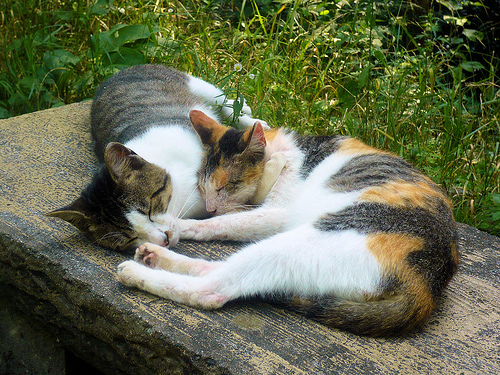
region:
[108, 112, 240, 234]
two cats are sleeping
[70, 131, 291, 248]
two cats are sleeping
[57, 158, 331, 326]
two cats are sleeping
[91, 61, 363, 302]
two cats are sleeping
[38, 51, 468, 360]
two cats, who are friends -or- momcat+kitten. hard to tell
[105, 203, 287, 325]
smaller cat has pink skin, seen beneath forelegs, lower hindlegs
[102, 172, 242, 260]
at least three, likely four, closed sleep eyes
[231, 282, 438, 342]
little cat's tail curled beneath little cat's thigh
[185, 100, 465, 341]
little calico has a vary bright orange in the mix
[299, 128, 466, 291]
three large grey+black stripe+spots on little, mostly white, calico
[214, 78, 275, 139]
two white hind feet of larger cat, with fluffy dandelions beside them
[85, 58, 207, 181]
long grey brown stripes on side of larger animal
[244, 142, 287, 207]
collar, other cat's forepaw, or bandage around little cat's neck? i am unsure, i am sorry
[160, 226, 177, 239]
one tiny light brown dot @ left side of larger cat's nose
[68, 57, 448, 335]
two reclined cats on bench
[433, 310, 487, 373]
grain of wood bench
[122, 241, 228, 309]
white feet on cat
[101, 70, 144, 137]
stripes on cat body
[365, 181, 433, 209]
orange on cat back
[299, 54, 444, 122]
green vegetation behind bench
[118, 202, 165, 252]
closed eyes of cat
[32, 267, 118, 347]
bark on wood bench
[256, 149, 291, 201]
paw around cat's neck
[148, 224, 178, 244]
nose on cat face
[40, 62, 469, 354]
aw... the kittys sleep together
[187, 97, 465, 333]
one is a calico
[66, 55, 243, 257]
the other is more a tabby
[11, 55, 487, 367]
they appear to be lying on a bench or a wall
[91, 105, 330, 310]
the cats seem to be connected to each other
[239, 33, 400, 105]
the grass & weeds are very tall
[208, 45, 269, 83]
tiny asters bloom in the weeds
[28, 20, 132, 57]
an overgrown garden is the perfect place for their nap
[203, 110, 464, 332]
this kitty has an amazing amount of orange color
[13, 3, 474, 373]
such a sweet picture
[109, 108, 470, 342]
the cats are laying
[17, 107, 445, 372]
the cats are on bench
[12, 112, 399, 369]
the bench is tan nad brown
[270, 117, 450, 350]
the cat is striped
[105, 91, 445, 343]
the cats are sleeping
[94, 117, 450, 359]
two cats are sleeping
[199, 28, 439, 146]
sunlight on the grass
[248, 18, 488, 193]
grass behind the bench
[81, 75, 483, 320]
two cats on bench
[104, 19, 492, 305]
grass behind the grass